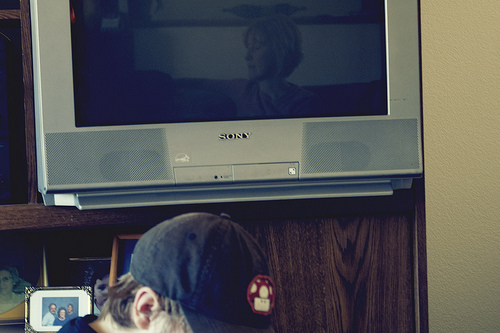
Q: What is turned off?
A: TV.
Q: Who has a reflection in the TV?
A: A woman.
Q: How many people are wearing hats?
A: One.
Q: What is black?
A: Hat.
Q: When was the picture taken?
A: Daytime.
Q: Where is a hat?
A: On man's head.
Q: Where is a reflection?
A: On TV screen.